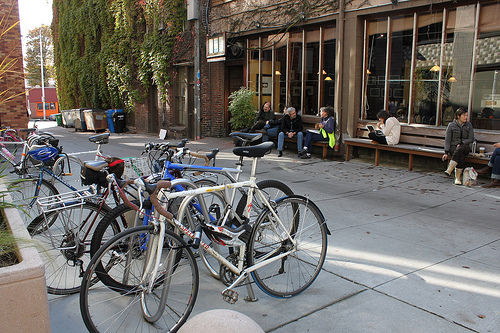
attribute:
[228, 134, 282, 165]
seat — black , curved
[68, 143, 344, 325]
bicycle — black and white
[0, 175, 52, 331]
concrete planter — concrete  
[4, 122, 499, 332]
sidewalk — stone , cement , paved 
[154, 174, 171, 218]
handle — tan 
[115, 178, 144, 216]
handle — tan 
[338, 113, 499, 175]
bench — wooden 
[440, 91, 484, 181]
person — sitting 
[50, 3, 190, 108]
ivy — growing 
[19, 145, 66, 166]
helmet — blue , hanging 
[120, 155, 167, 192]
basket — Empty 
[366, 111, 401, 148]
woman — working 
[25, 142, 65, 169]
helmet — Blue 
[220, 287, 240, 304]
bike pedal — metal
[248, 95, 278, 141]
person — sitting 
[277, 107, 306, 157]
person — sitting 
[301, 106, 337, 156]
person — sitting 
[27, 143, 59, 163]
helmet — blue 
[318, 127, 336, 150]
sweater — bright green , tied 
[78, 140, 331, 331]
bicycle — parked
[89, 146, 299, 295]
bicycle — parked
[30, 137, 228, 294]
bicycle — parked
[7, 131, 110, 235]
bicycle — parked